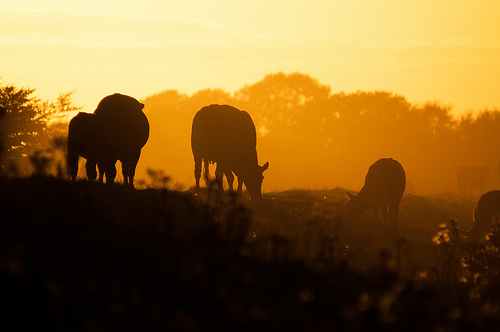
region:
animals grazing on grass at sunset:
[63, 90, 153, 177]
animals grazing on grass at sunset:
[183, 102, 273, 201]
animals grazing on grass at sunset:
[333, 155, 413, 236]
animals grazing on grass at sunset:
[443, 175, 491, 260]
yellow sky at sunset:
[21, 7, 476, 64]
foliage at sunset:
[10, 195, 270, 325]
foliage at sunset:
[266, 207, 463, 316]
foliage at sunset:
[270, 84, 346, 176]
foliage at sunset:
[423, 120, 487, 185]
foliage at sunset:
[13, 108, 53, 164]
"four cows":
[55, 86, 440, 224]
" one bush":
[0, 75, 75, 170]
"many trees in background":
[5, 60, 497, 195]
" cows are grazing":
[40, 75, 495, 230]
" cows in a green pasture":
[0, 80, 495, 315]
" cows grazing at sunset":
[5, 10, 497, 281]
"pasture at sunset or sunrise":
[0, 5, 495, 320]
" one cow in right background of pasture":
[445, 155, 495, 190]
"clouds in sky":
[1, 5, 496, 66]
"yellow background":
[2, 67, 497, 190]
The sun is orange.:
[27, 18, 487, 152]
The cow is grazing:
[173, 86, 274, 220]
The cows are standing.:
[39, 75, 401, 245]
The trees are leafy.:
[107, 53, 408, 161]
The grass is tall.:
[180, 208, 491, 318]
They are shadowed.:
[29, 95, 490, 296]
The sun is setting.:
[30, 21, 498, 239]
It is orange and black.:
[10, 15, 494, 323]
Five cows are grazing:
[57, 91, 497, 272]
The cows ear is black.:
[249, 152, 284, 187]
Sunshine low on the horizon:
[27, 34, 490, 212]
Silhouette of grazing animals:
[48, 79, 320, 216]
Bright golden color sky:
[91, 11, 484, 229]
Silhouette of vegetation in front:
[24, 143, 443, 323]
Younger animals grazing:
[291, 133, 498, 260]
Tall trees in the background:
[96, 69, 498, 183]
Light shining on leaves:
[396, 194, 498, 324]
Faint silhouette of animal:
[425, 148, 499, 220]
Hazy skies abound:
[11, 3, 274, 83]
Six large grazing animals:
[36, 61, 498, 254]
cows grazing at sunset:
[23, 48, 470, 264]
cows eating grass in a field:
[38, 70, 288, 230]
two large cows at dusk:
[65, 81, 295, 234]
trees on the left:
[0, 75, 112, 190]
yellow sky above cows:
[15, 10, 478, 92]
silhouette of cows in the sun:
[73, 53, 422, 268]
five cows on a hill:
[58, 97, 493, 287]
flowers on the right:
[410, 213, 494, 310]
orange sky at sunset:
[51, 31, 460, 231]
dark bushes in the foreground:
[15, 179, 282, 330]